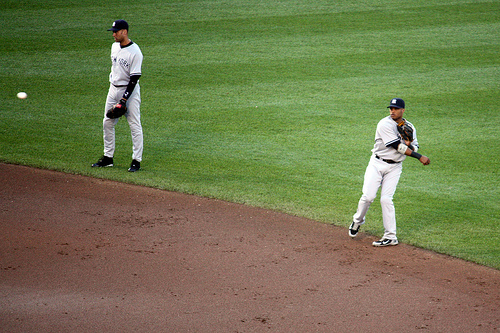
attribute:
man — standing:
[91, 19, 143, 173]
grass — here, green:
[0, 2, 499, 270]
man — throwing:
[349, 99, 427, 248]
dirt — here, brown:
[2, 161, 497, 332]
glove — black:
[107, 105, 127, 120]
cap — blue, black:
[107, 19, 128, 33]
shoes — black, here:
[91, 156, 140, 173]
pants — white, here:
[103, 84, 143, 165]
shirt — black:
[110, 42, 143, 99]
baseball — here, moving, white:
[16, 91, 27, 99]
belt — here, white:
[372, 153, 402, 166]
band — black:
[411, 150, 422, 161]